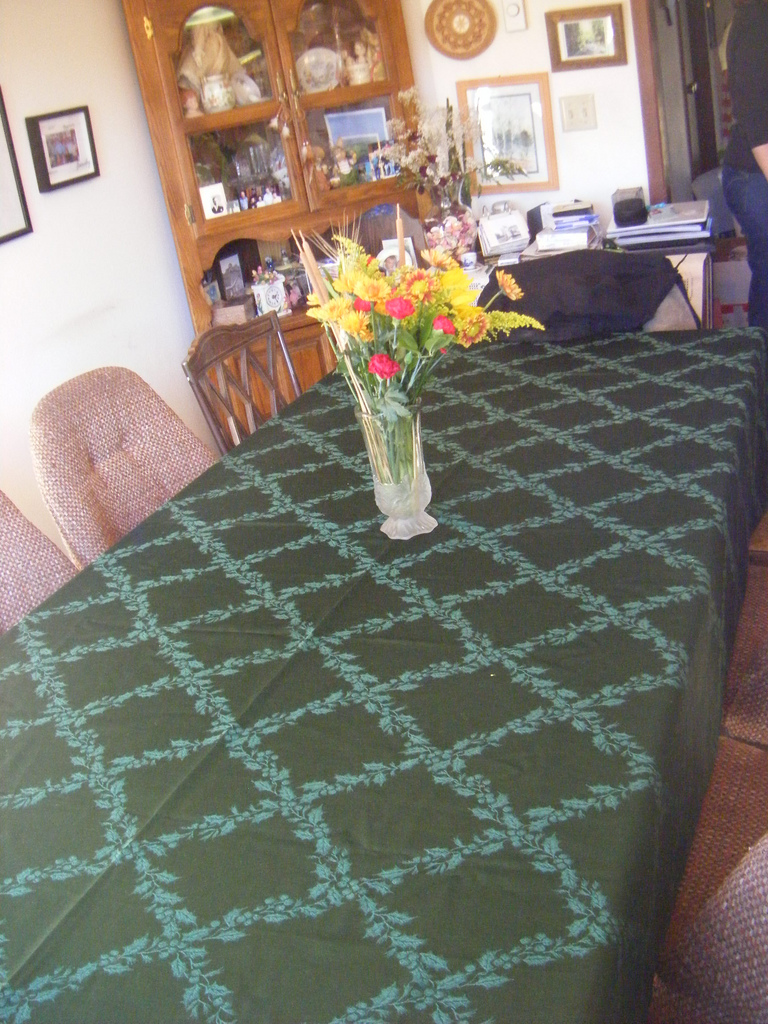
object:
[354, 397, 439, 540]
vase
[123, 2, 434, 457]
cabinet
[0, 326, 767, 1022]
cloth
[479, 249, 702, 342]
coat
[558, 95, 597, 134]
switches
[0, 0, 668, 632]
wall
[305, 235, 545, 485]
flowers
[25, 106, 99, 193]
picture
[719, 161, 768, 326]
jeans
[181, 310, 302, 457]
chair